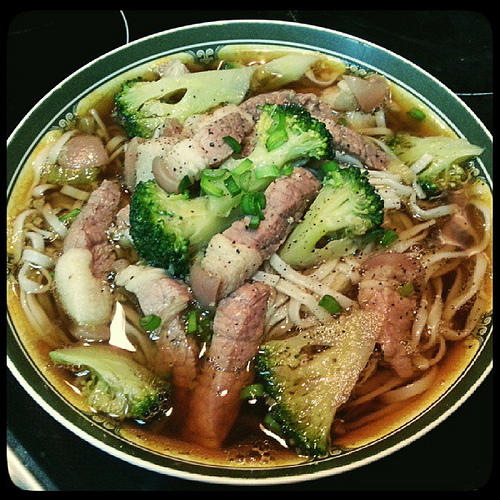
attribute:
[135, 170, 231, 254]
brocolli — green, bowl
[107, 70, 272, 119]
brocolli — green, bowl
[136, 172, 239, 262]
brocolli — bowl, green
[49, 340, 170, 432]
brocolli — green, bowl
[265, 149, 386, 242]
brocolli — bowl, green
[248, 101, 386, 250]
brocolli — bowl, green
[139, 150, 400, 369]
food — dish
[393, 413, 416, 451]
plate — food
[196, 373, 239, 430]
meat — plate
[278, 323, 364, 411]
veggies — plate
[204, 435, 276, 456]
juice — tan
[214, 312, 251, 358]
meat — juice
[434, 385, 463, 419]
rim — green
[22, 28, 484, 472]
bowl — food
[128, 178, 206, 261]
brociolli — green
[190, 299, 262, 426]
meat — pink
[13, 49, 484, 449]
meal — asian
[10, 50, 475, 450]
soup — asian, style, steak, vegetable, Asian-inspired 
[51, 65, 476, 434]
broccoli — green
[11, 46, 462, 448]
noodles — wild, rice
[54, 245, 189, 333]
florets — white, cauliflower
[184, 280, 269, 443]
meat — red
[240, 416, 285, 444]
broth — brown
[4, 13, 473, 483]
bowl — food, white, round, green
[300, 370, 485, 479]
rim — green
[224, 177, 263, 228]
onions — spring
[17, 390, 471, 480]
trim — green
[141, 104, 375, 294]
broccoli — steamed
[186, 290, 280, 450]
steak — cooked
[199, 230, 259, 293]
fat — white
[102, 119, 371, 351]
seasoning — black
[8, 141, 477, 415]
noodles — white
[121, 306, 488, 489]
broth — brown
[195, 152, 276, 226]
onion — chopped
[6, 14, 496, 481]
dish — cooked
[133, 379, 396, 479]
sauce — brown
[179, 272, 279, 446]
beef piece — sliced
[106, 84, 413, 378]
pepper — black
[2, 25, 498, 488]
bowl rim — blue, white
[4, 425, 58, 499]
fork — silver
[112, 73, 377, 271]
broccoli — green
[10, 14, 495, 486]
rim — green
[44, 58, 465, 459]
broth — brown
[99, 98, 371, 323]
pepper — black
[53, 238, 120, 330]
piece — large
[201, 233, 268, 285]
meat — fat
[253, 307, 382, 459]
broccoli — chunk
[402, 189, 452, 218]
asian noodle — strip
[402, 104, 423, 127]
chive — floating 